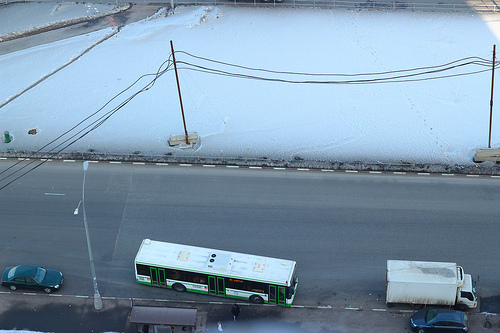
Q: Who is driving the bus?
A: Bus driver.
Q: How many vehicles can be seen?
A: Four.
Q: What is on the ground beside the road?
A: Snow.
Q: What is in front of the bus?
A: Truck.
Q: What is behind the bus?
A: Car.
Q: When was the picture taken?
A: Day time.